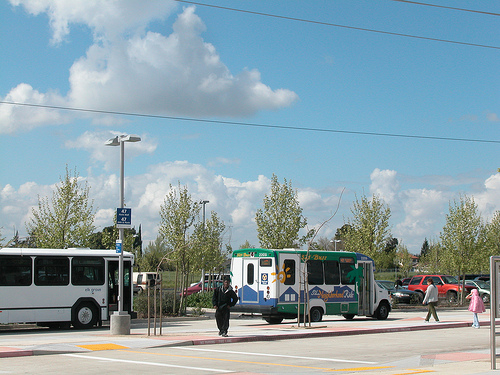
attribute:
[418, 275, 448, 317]
person — male, slim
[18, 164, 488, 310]
trees — young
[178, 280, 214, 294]
car — burgundy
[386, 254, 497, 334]
car — red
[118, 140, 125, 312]
post — white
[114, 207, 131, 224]
sign — blue and white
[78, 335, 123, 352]
paint — yellow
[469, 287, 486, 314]
coat — pink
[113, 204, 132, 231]
sign — blue and white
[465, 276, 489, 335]
dress — pink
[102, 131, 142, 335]
lamp — night lamp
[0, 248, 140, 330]
bus — white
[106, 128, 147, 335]
lamppost — lamp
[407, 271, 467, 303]
suv — orange-red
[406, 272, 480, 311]
suv — red and black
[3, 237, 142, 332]
city bus — large, white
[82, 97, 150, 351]
lamp — street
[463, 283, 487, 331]
girl — little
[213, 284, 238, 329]
dress — black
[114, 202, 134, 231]
signs — bus